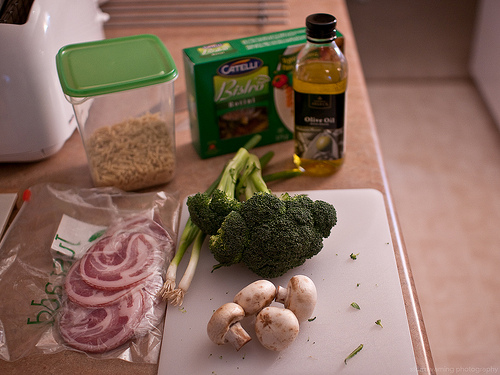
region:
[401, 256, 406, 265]
part of a table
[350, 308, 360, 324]
part of a board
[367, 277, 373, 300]
edge of a board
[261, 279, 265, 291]
part of an onion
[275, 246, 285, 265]
part of a vegetable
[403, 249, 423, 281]
edge of a table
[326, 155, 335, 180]
part of a bottle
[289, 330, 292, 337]
part of an onion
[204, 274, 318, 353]
four white button mushrooms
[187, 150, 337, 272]
green bunch of broccoli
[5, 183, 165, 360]
meat in a clear plastic bag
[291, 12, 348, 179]
olive oil is on the counter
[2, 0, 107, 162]
white toaster on the counter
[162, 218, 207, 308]
root ends of green onion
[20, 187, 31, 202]
red slider to close plastic bag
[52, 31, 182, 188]
plastic container with green lid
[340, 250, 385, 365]
green bits of broccoli on cutting board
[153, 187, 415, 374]
white plastic cutting board with food on it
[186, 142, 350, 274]
fresh broccoli on cutting board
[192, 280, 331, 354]
four white mushrooms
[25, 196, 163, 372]
some slices of red meat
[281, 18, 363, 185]
a bottle of olive oil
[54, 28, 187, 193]
a container with a green lid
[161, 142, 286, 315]
two green onions on cutting board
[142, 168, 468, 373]
a white plastic cutting board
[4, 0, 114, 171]
a white toaster next to container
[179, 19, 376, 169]
a box of Catelli Bistro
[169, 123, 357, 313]
green veggies on a cutting board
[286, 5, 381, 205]
small bottle of olive oil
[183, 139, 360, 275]
crowns of broccoli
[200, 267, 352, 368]
four mushrooms on cutting board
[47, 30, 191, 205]
container of pasta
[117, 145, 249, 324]
two spring onions on cutting board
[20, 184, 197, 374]
packet of bacon strips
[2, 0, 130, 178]
white toaster on table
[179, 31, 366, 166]
green box on table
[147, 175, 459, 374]
white cutting board on table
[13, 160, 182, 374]
clear plastic bag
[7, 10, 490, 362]
Food sitting on kitchen counter top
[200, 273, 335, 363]
Mushrooms on cutting board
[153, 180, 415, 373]
White cutting board with vegetables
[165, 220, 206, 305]
Green onions on cutting board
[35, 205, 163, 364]
Raw meat in plastic baggie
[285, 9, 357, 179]
Bottle of olive oil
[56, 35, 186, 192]
Plastic container partly filled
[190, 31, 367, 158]
Package of Catelli Bistro food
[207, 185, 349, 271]
Green vegetable on cutting board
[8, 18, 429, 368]
Food sitting on wooden counter